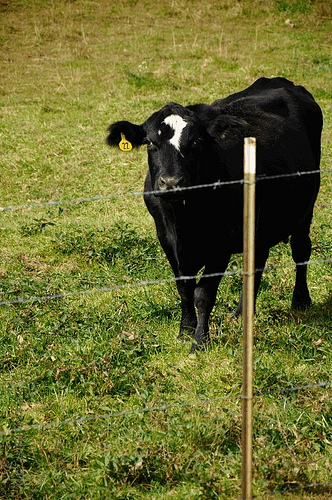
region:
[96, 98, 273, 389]
the cow is black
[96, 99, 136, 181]
a tag in cow's ear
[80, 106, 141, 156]
a tag in cow's ear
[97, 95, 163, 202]
a tag in cow's ear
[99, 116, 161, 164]
a tag in cow's ear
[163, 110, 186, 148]
white marking on cow's head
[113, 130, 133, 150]
yellow tag on cow's ear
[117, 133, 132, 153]
black numbers on yellow background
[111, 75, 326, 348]
black cow standing next to fence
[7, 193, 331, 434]
three lines of barbed wire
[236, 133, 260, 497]
rod barbed wire is attached to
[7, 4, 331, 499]
grass field cow is standing on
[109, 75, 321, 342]
black cow with white marking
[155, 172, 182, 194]
black nose of cow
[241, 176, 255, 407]
ties attaching wire to rod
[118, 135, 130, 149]
Tag on cow's ear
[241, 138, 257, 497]
Pasture land fence post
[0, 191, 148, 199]
Barbed wire pasture fence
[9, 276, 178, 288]
Barbed wire pasture fence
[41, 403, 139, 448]
part of green grass pasture land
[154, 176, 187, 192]
Nose of black cow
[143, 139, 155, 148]
Eye of black cow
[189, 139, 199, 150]
Eye of black cow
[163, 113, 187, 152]
White blaze on cow's face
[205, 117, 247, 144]
Ear of black cow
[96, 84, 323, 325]
the cow on the grass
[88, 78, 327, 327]
the cow beside the fence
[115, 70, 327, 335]
the cow is tagged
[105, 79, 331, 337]
the cow is black with a white spot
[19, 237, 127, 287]
the grass is short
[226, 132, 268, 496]
the fence post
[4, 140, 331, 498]
the fence is made of barbed wire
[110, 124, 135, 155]
the tag on the ear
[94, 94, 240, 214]
the head of the cow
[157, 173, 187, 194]
the nose of the cow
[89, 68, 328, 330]
the cow is black with white spot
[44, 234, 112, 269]
the grass is short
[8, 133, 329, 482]
the fence is barbed wire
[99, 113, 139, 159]
the tag in the ear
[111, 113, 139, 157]
the tag is yellow